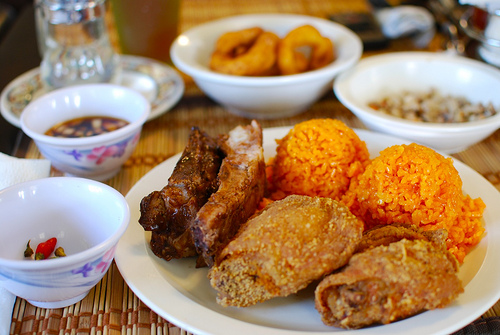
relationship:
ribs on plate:
[131, 108, 273, 253] [112, 91, 495, 293]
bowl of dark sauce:
[19, 83, 150, 180] [43, 108, 130, 137]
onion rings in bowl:
[209, 22, 336, 74] [170, 10, 362, 118]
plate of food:
[114, 120, 499, 334] [148, 115, 477, 325]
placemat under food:
[8, 279, 172, 334] [2, 13, 498, 327]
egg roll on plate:
[312, 228, 465, 333] [114, 120, 499, 334]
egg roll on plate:
[202, 186, 370, 305] [114, 120, 499, 334]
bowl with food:
[334, 47, 499, 153] [402, 83, 482, 119]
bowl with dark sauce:
[19, 83, 150, 180] [43, 108, 130, 137]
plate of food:
[114, 120, 499, 334] [136, 124, 229, 261]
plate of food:
[114, 120, 499, 334] [188, 117, 270, 268]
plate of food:
[114, 120, 499, 334] [271, 116, 371, 203]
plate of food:
[114, 120, 499, 334] [347, 141, 487, 263]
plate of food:
[114, 120, 499, 334] [209, 190, 364, 308]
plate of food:
[114, 120, 499, 334] [311, 222, 466, 331]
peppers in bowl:
[4, 209, 90, 271] [1, 175, 131, 309]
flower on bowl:
[67, 260, 98, 282] [1, 175, 131, 309]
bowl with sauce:
[19, 83, 150, 180] [42, 111, 126, 137]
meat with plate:
[144, 115, 244, 272] [114, 120, 499, 334]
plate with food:
[114, 120, 499, 334] [148, 115, 477, 325]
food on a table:
[148, 115, 477, 325] [0, 61, 498, 331]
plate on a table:
[114, 120, 499, 334] [12, 46, 477, 296]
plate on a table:
[114, 120, 499, 334] [64, 71, 478, 265]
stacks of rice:
[267, 108, 479, 235] [256, 112, 487, 272]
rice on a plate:
[274, 114, 489, 275] [114, 120, 499, 334]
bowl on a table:
[1, 175, 131, 309] [9, 300, 146, 332]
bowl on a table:
[19, 83, 150, 180] [9, 300, 146, 332]